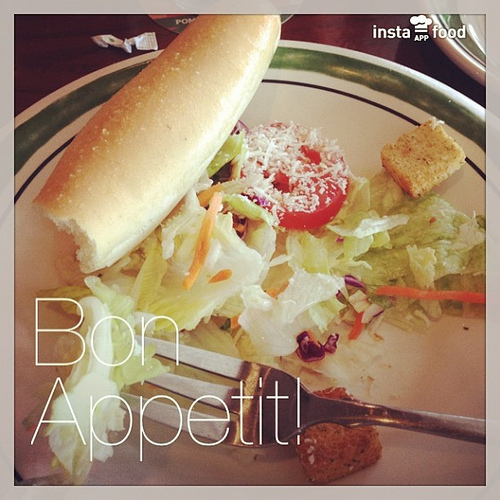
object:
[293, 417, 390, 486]
crouton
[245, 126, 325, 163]
chair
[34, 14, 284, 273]
bread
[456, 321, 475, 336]
plate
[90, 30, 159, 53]
straw wrapper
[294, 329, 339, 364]
cabbage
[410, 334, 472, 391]
part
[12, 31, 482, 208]
green stripe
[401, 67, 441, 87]
edge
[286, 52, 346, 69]
green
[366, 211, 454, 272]
lettuce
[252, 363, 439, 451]
handle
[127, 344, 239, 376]
prong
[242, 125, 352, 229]
tomato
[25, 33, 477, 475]
food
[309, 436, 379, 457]
cake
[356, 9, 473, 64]
logo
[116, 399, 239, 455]
prong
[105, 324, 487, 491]
fork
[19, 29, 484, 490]
dish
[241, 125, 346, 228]
cheese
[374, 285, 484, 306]
carrot piece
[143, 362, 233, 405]
prong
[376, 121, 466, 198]
crouton